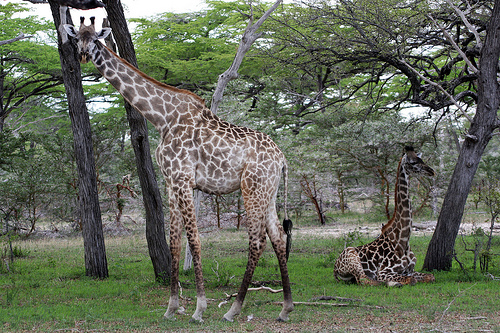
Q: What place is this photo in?
A: It is at the park.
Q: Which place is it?
A: It is a park.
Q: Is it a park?
A: Yes, it is a park.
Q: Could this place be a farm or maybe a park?
A: It is a park.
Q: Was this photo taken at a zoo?
A: No, the picture was taken in a park.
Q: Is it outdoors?
A: Yes, it is outdoors.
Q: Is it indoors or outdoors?
A: It is outdoors.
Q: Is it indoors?
A: No, it is outdoors.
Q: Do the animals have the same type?
A: Yes, all the animals are giraffes.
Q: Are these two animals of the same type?
A: Yes, all the animals are giraffes.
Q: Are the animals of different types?
A: No, all the animals are giraffes.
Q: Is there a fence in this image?
A: No, there are no fences.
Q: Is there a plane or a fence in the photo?
A: No, there are no fences or airplanes.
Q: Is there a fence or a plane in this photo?
A: No, there are no fences or airplanes.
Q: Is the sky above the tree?
A: Yes, the sky is above the tree.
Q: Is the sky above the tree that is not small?
A: Yes, the sky is above the tree.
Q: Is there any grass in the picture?
A: Yes, there is grass.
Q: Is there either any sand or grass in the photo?
A: Yes, there is grass.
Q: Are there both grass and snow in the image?
A: No, there is grass but no snow.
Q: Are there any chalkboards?
A: No, there are no chalkboards.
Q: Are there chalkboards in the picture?
A: No, there are no chalkboards.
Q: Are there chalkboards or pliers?
A: No, there are no chalkboards or pliers.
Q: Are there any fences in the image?
A: No, there are no fences.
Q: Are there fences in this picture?
A: No, there are no fences.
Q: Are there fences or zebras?
A: No, there are no fences or zebras.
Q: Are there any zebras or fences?
A: No, there are no fences or zebras.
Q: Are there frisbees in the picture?
A: No, there are no frisbees.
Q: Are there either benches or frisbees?
A: No, there are no frisbees or benches.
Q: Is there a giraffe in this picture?
A: Yes, there is a giraffe.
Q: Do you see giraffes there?
A: Yes, there is a giraffe.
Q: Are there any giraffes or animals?
A: Yes, there is a giraffe.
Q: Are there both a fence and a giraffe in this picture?
A: No, there is a giraffe but no fences.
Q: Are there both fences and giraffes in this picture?
A: No, there is a giraffe but no fences.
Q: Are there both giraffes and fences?
A: No, there is a giraffe but no fences.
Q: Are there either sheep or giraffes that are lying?
A: Yes, the giraffe is lying.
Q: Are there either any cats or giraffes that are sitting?
A: Yes, the giraffe is sitting.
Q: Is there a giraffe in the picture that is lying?
A: Yes, there is a giraffe that is lying.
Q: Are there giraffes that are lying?
A: Yes, there is a giraffe that is lying.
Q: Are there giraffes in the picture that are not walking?
A: Yes, there is a giraffe that is lying.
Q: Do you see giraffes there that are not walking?
A: Yes, there is a giraffe that is lying .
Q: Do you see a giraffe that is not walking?
A: Yes, there is a giraffe that is lying .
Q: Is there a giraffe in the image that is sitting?
A: Yes, there is a giraffe that is sitting.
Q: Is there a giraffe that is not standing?
A: Yes, there is a giraffe that is sitting.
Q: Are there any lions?
A: No, there are no lions.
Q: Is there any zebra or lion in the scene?
A: No, there are no lions or zebras.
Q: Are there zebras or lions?
A: No, there are no lions or zebras.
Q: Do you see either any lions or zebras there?
A: No, there are no lions or zebras.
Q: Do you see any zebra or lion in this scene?
A: No, there are no lions or zebras.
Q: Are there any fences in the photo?
A: No, there are no fences.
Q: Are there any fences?
A: No, there are no fences.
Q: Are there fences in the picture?
A: No, there are no fences.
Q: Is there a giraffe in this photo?
A: Yes, there is a giraffe.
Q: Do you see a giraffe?
A: Yes, there is a giraffe.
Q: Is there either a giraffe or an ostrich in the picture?
A: Yes, there is a giraffe.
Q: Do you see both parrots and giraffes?
A: No, there is a giraffe but no parrots.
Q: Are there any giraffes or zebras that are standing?
A: Yes, the giraffe is standing.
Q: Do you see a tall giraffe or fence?
A: Yes, there is a tall giraffe.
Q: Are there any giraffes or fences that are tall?
A: Yes, the giraffe is tall.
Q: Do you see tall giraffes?
A: Yes, there is a tall giraffe.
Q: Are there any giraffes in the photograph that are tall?
A: Yes, there is a giraffe that is tall.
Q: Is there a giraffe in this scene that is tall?
A: Yes, there is a giraffe that is tall.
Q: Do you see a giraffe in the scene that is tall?
A: Yes, there is a giraffe that is tall.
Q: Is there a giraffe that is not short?
A: Yes, there is a tall giraffe.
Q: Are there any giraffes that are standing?
A: Yes, there is a giraffe that is standing.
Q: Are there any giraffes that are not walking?
A: Yes, there is a giraffe that is standing.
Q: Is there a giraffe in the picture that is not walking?
A: Yes, there is a giraffe that is standing.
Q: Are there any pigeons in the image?
A: No, there are no pigeons.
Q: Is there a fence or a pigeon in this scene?
A: No, there are no pigeons or fences.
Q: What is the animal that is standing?
A: The animal is a giraffe.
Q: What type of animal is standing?
A: The animal is a giraffe.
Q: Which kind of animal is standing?
A: The animal is a giraffe.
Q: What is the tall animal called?
A: The animal is a giraffe.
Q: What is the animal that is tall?
A: The animal is a giraffe.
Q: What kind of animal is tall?
A: The animal is a giraffe.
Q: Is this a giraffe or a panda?
A: This is a giraffe.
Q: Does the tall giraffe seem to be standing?
A: Yes, the giraffe is standing.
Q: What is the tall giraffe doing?
A: The giraffe is standing.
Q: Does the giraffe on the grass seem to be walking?
A: No, the giraffe is standing.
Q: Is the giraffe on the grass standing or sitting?
A: The giraffe is standing.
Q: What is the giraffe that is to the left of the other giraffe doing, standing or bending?
A: The giraffe is standing.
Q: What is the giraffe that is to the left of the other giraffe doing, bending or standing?
A: The giraffe is standing.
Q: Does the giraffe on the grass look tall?
A: Yes, the giraffe is tall.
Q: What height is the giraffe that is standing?
A: The giraffe is tall.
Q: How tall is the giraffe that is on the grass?
A: The giraffe is tall.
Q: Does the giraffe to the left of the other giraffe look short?
A: No, the giraffe is tall.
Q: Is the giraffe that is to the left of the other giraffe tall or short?
A: The giraffe is tall.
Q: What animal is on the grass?
A: The giraffe is on the grass.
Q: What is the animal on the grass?
A: The animal is a giraffe.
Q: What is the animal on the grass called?
A: The animal is a giraffe.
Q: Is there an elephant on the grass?
A: No, there is a giraffe on the grass.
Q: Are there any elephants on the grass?
A: No, there is a giraffe on the grass.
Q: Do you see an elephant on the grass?
A: No, there is a giraffe on the grass.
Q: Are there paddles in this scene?
A: No, there are no paddles.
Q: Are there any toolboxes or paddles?
A: No, there are no paddles or toolboxes.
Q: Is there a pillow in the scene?
A: No, there are no pillows.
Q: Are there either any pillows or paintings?
A: No, there are no pillows or paintings.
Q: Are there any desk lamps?
A: No, there are no desk lamps.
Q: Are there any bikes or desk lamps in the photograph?
A: No, there are no desk lamps or bikes.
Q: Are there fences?
A: No, there are no fences.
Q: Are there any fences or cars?
A: No, there are no fences or cars.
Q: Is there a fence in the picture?
A: No, there are no fences.